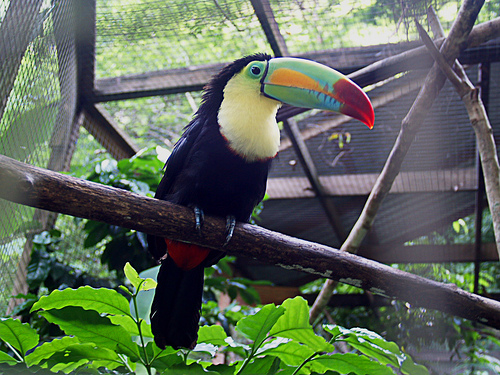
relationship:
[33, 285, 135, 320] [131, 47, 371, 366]
leaf under bird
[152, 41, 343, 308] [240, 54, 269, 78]
bird has lined eye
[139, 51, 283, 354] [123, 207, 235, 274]
feathers on a rear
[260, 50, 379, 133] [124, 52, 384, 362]
beak of bird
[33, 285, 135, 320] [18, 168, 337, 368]
leaf on tree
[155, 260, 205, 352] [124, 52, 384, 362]
tail of bird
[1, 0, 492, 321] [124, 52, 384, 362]
cage behind bird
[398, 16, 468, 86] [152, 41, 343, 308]
branch above bird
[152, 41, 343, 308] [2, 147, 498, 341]
bird on branch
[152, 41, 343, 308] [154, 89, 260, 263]
bird with feathers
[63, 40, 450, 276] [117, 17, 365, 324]
fencing behind bird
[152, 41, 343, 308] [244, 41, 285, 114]
bird with eyes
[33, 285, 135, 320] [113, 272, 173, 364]
leaf to stem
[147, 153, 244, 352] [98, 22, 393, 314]
feathers on parrot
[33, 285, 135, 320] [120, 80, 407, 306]
leaf behind parrot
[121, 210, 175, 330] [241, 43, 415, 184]
tips of beak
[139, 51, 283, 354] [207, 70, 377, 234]
feathers on neck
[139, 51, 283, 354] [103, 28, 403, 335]
feathers under bird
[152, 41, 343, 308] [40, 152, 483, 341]
bird on stick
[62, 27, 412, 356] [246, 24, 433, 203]
bird with beak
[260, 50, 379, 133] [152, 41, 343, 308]
beak of bird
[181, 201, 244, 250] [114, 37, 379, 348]
feet of toucan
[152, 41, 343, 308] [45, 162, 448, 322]
bird perched on branch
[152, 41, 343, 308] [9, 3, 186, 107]
bird inside enclosure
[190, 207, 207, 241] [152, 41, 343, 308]
claw on bird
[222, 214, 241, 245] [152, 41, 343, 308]
claw on bird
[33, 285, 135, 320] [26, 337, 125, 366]
leaf next leaf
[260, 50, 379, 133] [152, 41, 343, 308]
beak on bird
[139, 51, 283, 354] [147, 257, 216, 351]
feathers on tail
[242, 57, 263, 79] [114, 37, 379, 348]
eye of toucan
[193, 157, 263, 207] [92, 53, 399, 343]
plummage of toucan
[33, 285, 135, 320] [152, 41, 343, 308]
leaf beneath bird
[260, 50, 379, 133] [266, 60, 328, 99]
beak has streak